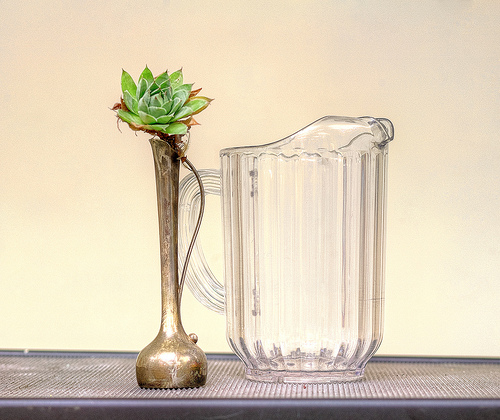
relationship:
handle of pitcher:
[179, 169, 226, 318] [207, 117, 396, 382]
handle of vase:
[180, 141, 204, 301] [136, 134, 206, 390]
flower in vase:
[110, 64, 215, 154] [136, 134, 206, 390]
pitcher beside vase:
[207, 117, 396, 382] [136, 134, 206, 390]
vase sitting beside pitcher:
[136, 134, 206, 390] [207, 117, 396, 382]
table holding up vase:
[0, 350, 499, 419] [136, 134, 206, 390]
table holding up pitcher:
[0, 350, 499, 419] [207, 117, 396, 382]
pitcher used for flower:
[207, 117, 396, 382] [110, 64, 215, 154]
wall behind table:
[2, 1, 499, 357] [0, 350, 499, 419]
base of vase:
[136, 330, 206, 390] [136, 134, 206, 390]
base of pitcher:
[247, 369, 366, 382] [207, 117, 396, 382]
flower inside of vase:
[110, 64, 215, 154] [136, 134, 206, 390]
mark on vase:
[168, 364, 177, 385] [136, 134, 206, 390]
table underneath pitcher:
[0, 350, 499, 419] [207, 117, 396, 382]